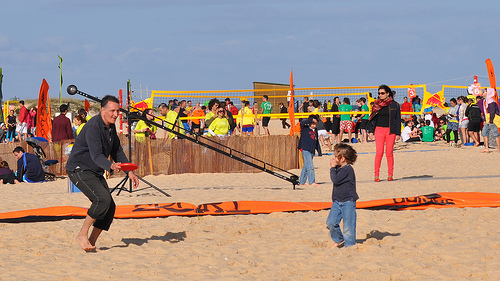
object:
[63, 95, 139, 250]
man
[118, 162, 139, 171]
frisbee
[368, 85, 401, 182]
people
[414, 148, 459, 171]
beach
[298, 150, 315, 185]
jeans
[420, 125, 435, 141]
shirt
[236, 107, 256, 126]
shirt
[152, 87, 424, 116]
net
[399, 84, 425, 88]
top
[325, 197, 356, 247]
jeans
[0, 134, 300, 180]
fence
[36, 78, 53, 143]
banner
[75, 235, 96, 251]
feet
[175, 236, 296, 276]
sand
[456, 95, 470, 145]
woman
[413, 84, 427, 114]
trim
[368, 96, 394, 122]
scarf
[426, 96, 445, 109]
bull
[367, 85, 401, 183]
woman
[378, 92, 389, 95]
sunglasses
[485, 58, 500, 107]
flag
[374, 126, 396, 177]
jeans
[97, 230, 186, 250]
shadow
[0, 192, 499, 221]
banner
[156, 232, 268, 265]
ground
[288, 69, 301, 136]
sign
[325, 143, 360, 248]
kid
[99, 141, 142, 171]
disc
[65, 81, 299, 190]
equipment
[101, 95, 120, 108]
hair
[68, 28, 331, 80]
sky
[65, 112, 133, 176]
shirt